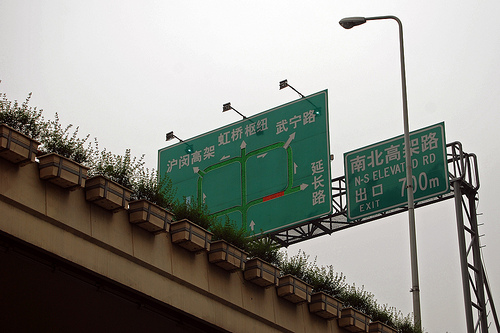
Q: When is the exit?
A: 700 m.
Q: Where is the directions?
A: Above the highway.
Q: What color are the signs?
A: Green with white letters.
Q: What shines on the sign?
A: Automated lights.